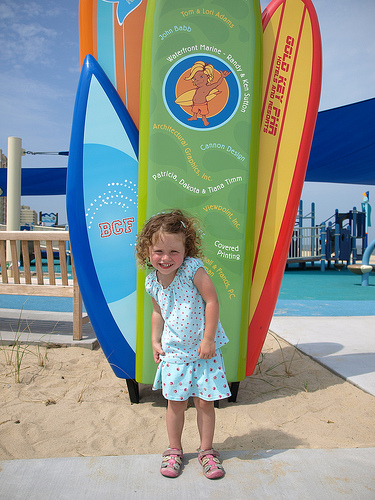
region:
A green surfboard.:
[132, 1, 264, 209]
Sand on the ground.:
[4, 375, 141, 453]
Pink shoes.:
[154, 442, 238, 483]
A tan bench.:
[1, 227, 84, 346]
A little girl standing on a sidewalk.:
[128, 204, 246, 486]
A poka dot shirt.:
[140, 270, 220, 359]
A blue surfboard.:
[63, 58, 139, 368]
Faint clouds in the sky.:
[0, 0, 63, 121]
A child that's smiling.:
[134, 213, 251, 479]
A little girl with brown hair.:
[127, 204, 218, 314]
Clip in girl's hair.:
[172, 215, 192, 244]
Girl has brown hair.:
[186, 234, 203, 251]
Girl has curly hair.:
[134, 238, 166, 278]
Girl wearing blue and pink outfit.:
[160, 310, 211, 365]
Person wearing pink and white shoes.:
[156, 452, 238, 473]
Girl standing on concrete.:
[133, 436, 247, 495]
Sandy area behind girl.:
[30, 383, 118, 430]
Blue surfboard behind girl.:
[62, 186, 122, 294]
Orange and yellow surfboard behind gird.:
[248, 243, 279, 329]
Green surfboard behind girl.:
[212, 241, 236, 307]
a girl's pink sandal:
[195, 445, 227, 480]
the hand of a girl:
[196, 337, 219, 361]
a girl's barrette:
[178, 219, 189, 230]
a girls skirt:
[150, 357, 234, 400]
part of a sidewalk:
[268, 314, 371, 394]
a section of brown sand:
[1, 331, 374, 461]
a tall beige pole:
[5, 131, 24, 264]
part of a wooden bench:
[0, 231, 90, 341]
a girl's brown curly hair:
[133, 209, 203, 274]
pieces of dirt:
[265, 452, 290, 484]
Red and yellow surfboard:
[241, 0, 323, 404]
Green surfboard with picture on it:
[130, 0, 259, 402]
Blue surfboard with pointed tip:
[64, 52, 158, 392]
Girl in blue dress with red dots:
[131, 206, 239, 483]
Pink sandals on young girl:
[155, 442, 227, 480]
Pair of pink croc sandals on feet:
[156, 444, 231, 482]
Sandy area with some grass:
[0, 319, 371, 449]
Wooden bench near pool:
[0, 222, 100, 335]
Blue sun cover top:
[2, 97, 373, 196]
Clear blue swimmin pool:
[0, 260, 372, 322]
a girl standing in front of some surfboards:
[117, 216, 252, 481]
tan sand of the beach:
[53, 415, 121, 442]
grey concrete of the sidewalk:
[284, 459, 374, 497]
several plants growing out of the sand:
[4, 342, 62, 389]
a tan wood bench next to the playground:
[0, 224, 92, 325]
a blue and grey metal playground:
[287, 198, 371, 275]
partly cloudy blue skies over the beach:
[1, 64, 62, 124]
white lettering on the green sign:
[152, 164, 245, 198]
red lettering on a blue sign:
[99, 216, 132, 245]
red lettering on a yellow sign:
[264, 14, 299, 146]